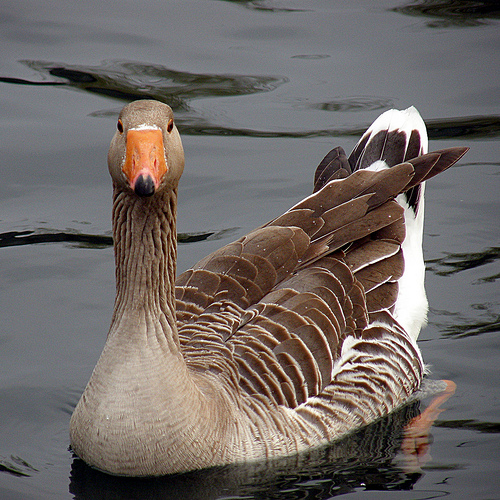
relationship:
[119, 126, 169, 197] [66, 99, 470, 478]
beak on a duck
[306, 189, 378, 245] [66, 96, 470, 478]
feather on duck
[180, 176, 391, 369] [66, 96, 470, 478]
feather on duck